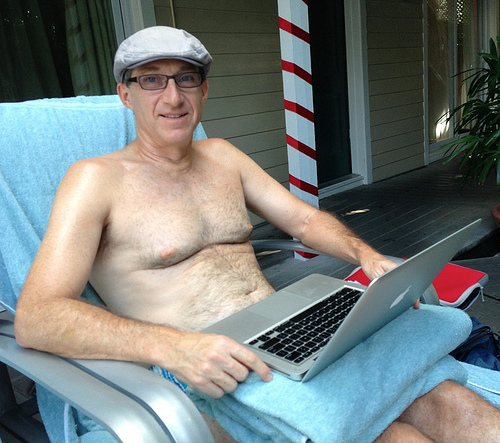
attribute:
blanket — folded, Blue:
[191, 319, 471, 439]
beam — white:
[266, 0, 321, 261]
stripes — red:
[276, 7, 313, 197]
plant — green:
[432, 49, 480, 200]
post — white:
[268, 1, 328, 263]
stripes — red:
[268, 0, 321, 260]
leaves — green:
[465, 100, 483, 149]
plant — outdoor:
[440, 36, 484, 202]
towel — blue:
[3, 88, 216, 320]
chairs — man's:
[0, 90, 473, 440]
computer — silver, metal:
[189, 214, 481, 381]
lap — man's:
[133, 313, 461, 428]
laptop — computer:
[187, 188, 483, 389]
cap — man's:
[90, 19, 222, 89]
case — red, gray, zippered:
[342, 236, 480, 313]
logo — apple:
[382, 279, 417, 312]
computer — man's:
[179, 219, 478, 390]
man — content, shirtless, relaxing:
[11, 25, 467, 425]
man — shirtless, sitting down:
[12, 20, 383, 434]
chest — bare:
[117, 179, 271, 319]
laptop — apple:
[192, 221, 483, 391]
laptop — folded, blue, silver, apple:
[185, 209, 476, 379]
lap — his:
[192, 317, 452, 439]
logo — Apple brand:
[388, 283, 413, 310]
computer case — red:
[344, 256, 488, 312]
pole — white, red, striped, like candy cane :
[276, 1, 319, 261]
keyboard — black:
[247, 287, 364, 363]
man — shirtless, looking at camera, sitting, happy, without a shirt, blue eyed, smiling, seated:
[13, 24, 498, 440]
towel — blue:
[0, 92, 500, 441]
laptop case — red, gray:
[342, 251, 490, 311]